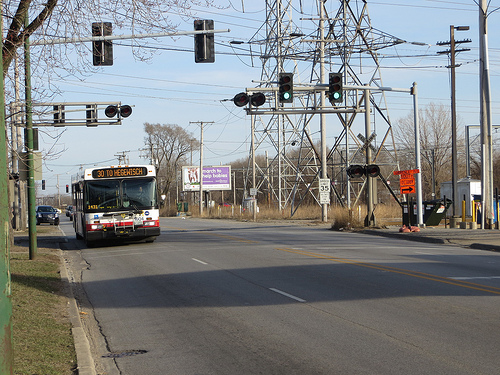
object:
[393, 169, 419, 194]
sign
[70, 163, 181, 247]
bus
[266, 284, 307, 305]
line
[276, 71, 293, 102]
light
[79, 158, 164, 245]
bus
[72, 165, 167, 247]
bus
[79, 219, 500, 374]
road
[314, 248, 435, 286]
line